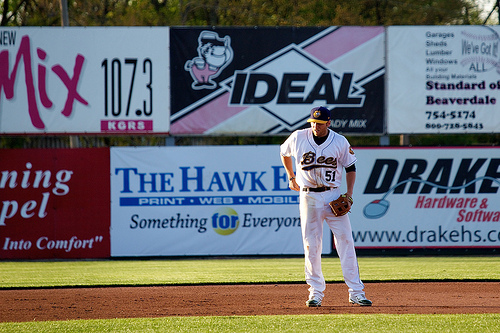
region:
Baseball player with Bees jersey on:
[278, 103, 370, 306]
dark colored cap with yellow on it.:
[304, 106, 330, 126]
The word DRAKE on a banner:
[361, 154, 498, 195]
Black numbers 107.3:
[98, 61, 155, 114]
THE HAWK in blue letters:
[112, 163, 270, 194]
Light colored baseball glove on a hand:
[327, 194, 354, 215]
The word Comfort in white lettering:
[37, 235, 94, 255]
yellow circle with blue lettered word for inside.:
[211, 209, 241, 236]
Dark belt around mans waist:
[302, 183, 334, 195]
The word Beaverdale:
[425, 95, 499, 107]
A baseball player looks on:
[246, 87, 413, 309]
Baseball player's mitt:
[297, 165, 384, 235]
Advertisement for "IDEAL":
[154, 16, 404, 140]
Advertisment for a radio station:
[0, 27, 172, 133]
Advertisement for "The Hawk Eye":
[122, 147, 312, 252]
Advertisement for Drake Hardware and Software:
[331, 145, 494, 256]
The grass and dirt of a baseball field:
[9, 262, 371, 331]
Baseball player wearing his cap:
[289, 102, 348, 154]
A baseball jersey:
[274, 124, 355, 198]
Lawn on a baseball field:
[14, 263, 293, 288]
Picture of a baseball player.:
[142, 21, 423, 313]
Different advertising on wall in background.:
[12, 35, 449, 246]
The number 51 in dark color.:
[321, 165, 344, 187]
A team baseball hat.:
[296, 98, 346, 132]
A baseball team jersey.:
[271, 124, 363, 193]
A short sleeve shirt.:
[281, 117, 357, 190]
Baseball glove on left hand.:
[329, 191, 359, 218]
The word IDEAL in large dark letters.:
[230, 62, 370, 112]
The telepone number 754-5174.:
[416, 103, 481, 122]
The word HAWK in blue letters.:
[175, 156, 274, 198]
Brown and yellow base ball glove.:
[317, 195, 356, 220]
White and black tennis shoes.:
[274, 290, 376, 320]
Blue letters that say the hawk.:
[107, 161, 284, 195]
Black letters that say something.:
[107, 213, 210, 236]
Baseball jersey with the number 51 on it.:
[276, 130, 346, 191]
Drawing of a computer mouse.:
[352, 170, 487, 234]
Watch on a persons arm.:
[277, 167, 304, 184]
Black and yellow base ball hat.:
[292, 99, 333, 131]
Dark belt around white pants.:
[290, 175, 344, 200]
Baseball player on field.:
[239, 95, 416, 323]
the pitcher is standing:
[274, 102, 394, 317]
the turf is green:
[105, 266, 170, 278]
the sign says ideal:
[220, 59, 366, 125]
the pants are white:
[296, 187, 362, 315]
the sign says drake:
[362, 153, 498, 204]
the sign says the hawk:
[110, 155, 270, 203]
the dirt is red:
[45, 286, 165, 308]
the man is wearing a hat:
[300, 103, 335, 155]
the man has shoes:
[297, 287, 380, 314]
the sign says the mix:
[4, 32, 96, 125]